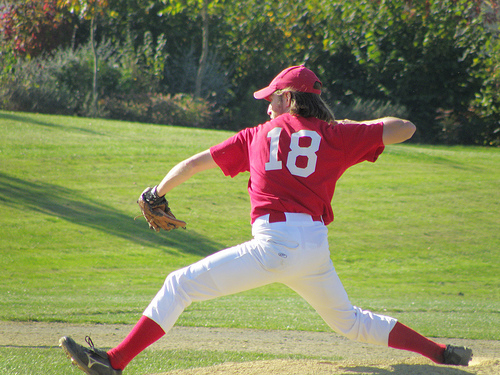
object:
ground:
[0, 110, 499, 374]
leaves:
[40, 15, 57, 26]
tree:
[0, 0, 499, 145]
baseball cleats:
[56, 332, 123, 373]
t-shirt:
[210, 108, 385, 226]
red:
[253, 188, 294, 210]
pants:
[143, 211, 397, 349]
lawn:
[0, 107, 499, 342]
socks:
[389, 320, 455, 366]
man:
[59, 63, 478, 374]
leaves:
[295, 20, 329, 38]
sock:
[107, 311, 165, 371]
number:
[285, 129, 324, 178]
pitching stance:
[57, 65, 474, 374]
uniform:
[143, 109, 399, 353]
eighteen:
[260, 126, 325, 178]